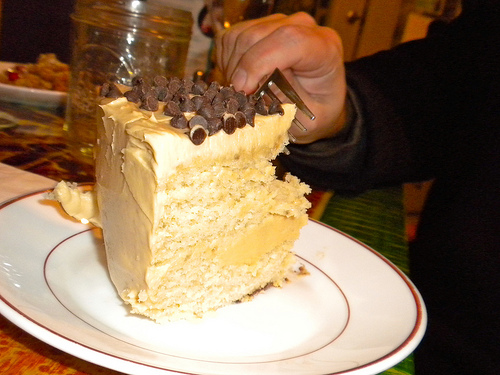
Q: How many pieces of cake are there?
A: 1.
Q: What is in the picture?
A: A slice of cake.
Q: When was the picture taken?
A: During a party.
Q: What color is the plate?
A: Red and white.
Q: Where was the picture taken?
A: At a party.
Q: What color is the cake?
A: Yellow.